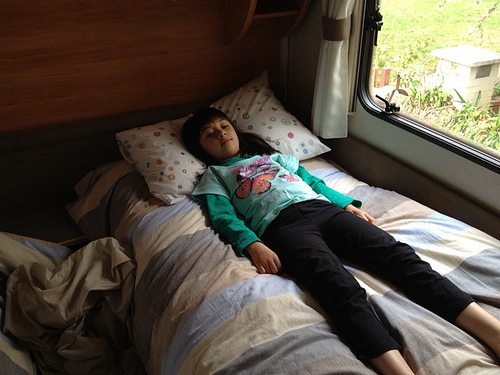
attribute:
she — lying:
[172, 101, 500, 374]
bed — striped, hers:
[62, 141, 499, 374]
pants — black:
[256, 189, 483, 370]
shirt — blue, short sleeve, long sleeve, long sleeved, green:
[196, 150, 340, 241]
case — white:
[103, 68, 333, 213]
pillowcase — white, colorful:
[116, 60, 342, 227]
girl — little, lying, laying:
[177, 101, 499, 373]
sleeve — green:
[293, 160, 367, 220]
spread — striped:
[78, 151, 472, 372]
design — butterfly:
[205, 148, 305, 213]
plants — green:
[370, 1, 499, 127]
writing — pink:
[226, 155, 276, 177]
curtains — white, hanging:
[306, 0, 369, 150]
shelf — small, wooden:
[220, 2, 316, 52]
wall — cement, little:
[438, 41, 500, 119]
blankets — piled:
[0, 199, 179, 374]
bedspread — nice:
[66, 138, 499, 371]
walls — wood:
[2, 2, 306, 293]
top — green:
[180, 137, 384, 266]